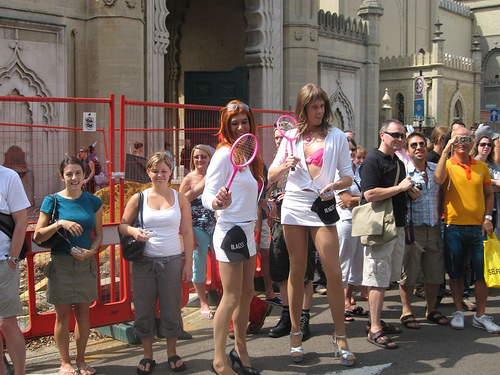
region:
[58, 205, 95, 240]
the blouse is blue in color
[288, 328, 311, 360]
the shoes are white in color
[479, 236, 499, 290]
the bag is yellow in color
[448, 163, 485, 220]
the shirt is orange in color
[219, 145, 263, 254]
the outfit is white in color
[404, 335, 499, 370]
the floor is rough and tarmaced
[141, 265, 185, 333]
the short is grey in color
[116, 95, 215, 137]
the gate is red in color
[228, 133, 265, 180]
the tennis bal net is pink in color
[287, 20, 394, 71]
the building roof is lime white in color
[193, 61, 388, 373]
two men dressed like women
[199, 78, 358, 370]
two transgender people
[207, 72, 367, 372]
two tall people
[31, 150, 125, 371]
she is wearing a blue shirt and a skirt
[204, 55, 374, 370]
they are holding pink rackets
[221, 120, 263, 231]
a pink badminton racket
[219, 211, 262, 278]
a black baseball cap attached to a skirt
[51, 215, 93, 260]
she has a camera around her wrist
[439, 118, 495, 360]
he is taking a photo with a camera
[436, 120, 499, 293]
he is wearing a yellow and orange polo shirt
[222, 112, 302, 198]
people holding tennis rackets.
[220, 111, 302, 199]
the rackets are pink.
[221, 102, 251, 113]
sunglasses on person's head.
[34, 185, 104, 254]
woman wearing blue shirt.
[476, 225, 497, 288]
man holding yellow bag.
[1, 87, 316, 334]
fence behind the people.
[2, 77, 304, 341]
the fence is red.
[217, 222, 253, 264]
hat on the person's waist.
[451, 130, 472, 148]
man holding a camera.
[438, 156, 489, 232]
man's shirt is yellow.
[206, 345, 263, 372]
Person wearing shoes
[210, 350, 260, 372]
Person is wearing shoes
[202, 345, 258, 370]
Person wearing heels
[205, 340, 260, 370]
Person is wearing heels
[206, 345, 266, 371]
Person wearing black shoes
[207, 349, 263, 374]
Person is wearing black shoes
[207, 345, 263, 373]
Person wearing black heels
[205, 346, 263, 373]
Person is wearing black heels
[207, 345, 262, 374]
Person wearing high heels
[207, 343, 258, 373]
Person wearing black high heels